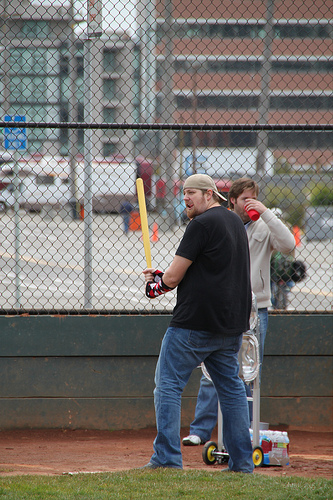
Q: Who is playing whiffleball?
A: The man wearing a cap.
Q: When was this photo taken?
A: Daylight hours.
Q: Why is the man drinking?
A: Thirst.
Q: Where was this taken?
A: Park in a city or town street.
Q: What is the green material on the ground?
A: Grass.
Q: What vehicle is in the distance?
A: A brown and white motorhome.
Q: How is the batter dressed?
A: Black t-shirt, blue jeans, cap.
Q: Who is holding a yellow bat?
A: The heavy man with a cap.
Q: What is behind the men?
A: Chain link fence.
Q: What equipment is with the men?
A: A hand truck.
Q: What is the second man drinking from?
A: Red cup.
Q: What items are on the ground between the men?
A: Water bottles and a dolly.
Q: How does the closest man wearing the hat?
A: Backwards.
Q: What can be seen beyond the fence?
A: Buildings.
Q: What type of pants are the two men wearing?
A: Blue jens.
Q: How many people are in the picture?
A: Two.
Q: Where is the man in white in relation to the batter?
A: Behind.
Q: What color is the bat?
A: Yellow.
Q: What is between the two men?
A: Dolly.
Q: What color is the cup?
A: Red.